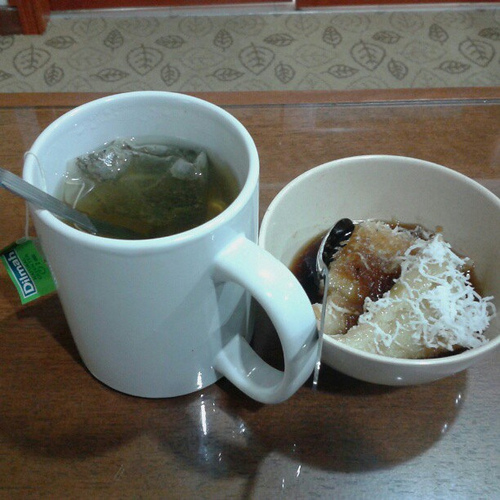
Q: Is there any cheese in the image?
A: Yes, there is cheese.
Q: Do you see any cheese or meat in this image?
A: Yes, there is cheese.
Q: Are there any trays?
A: No, there are no trays.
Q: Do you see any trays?
A: No, there are no trays.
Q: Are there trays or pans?
A: No, there are no trays or pans.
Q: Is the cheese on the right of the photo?
A: Yes, the cheese is on the right of the image.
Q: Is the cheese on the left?
A: No, the cheese is on the right of the image.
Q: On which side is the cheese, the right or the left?
A: The cheese is on the right of the image.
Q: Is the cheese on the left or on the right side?
A: The cheese is on the right of the image.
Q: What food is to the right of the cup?
A: The food is cheese.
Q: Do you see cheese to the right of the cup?
A: Yes, there is cheese to the right of the cup.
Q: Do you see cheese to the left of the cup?
A: No, the cheese is to the right of the cup.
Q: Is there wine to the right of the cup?
A: No, there is cheese to the right of the cup.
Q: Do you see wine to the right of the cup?
A: No, there is cheese to the right of the cup.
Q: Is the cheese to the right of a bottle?
A: No, the cheese is to the right of the cup.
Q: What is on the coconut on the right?
A: The cheese is on the coconut.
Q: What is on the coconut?
A: The cheese is on the coconut.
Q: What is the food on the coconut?
A: The food is cheese.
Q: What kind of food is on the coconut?
A: The food is cheese.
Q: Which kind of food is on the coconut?
A: The food is cheese.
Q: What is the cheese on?
A: The cheese is on the coconut.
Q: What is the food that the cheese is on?
A: The food is a coconut.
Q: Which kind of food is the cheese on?
A: The cheese is on the coconut.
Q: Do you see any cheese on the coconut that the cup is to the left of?
A: Yes, there is cheese on the coconut.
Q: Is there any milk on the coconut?
A: No, there is cheese on the coconut.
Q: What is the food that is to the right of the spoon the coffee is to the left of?
A: The food is cheese.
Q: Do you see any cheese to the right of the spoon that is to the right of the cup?
A: Yes, there is cheese to the right of the spoon.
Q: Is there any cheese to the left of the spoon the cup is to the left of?
A: No, the cheese is to the right of the spoon.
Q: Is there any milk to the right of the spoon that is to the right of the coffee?
A: No, there is cheese to the right of the spoon.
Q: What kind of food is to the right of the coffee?
A: The food is cheese.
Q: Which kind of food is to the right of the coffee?
A: The food is cheese.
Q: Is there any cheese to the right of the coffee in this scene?
A: Yes, there is cheese to the right of the coffee.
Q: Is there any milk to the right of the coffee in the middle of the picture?
A: No, there is cheese to the right of the coffee.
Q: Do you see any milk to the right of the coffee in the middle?
A: No, there is cheese to the right of the coffee.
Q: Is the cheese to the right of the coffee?
A: Yes, the cheese is to the right of the coffee.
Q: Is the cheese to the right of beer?
A: No, the cheese is to the right of the coffee.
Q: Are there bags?
A: Yes, there is a bag.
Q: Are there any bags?
A: Yes, there is a bag.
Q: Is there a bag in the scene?
A: Yes, there is a bag.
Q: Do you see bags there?
A: Yes, there is a bag.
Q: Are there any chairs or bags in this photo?
A: Yes, there is a bag.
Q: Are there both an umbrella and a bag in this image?
A: No, there is a bag but no umbrellas.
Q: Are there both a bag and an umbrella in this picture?
A: No, there is a bag but no umbrellas.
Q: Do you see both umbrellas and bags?
A: No, there is a bag but no umbrellas.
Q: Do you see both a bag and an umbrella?
A: No, there is a bag but no umbrellas.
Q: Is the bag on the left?
A: Yes, the bag is on the left of the image.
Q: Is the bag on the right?
A: No, the bag is on the left of the image.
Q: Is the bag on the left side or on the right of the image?
A: The bag is on the left of the image.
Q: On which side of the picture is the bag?
A: The bag is on the left of the image.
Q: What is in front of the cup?
A: The bag is in front of the cup.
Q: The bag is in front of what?
A: The bag is in front of the cup.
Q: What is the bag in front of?
A: The bag is in front of the cup.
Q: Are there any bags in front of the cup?
A: Yes, there is a bag in front of the cup.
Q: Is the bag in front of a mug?
A: No, the bag is in front of the cup.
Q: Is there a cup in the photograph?
A: Yes, there is a cup.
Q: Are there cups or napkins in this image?
A: Yes, there is a cup.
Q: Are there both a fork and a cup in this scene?
A: No, there is a cup but no forks.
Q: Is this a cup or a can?
A: This is a cup.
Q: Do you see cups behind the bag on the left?
A: Yes, there is a cup behind the bag.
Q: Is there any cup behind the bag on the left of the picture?
A: Yes, there is a cup behind the bag.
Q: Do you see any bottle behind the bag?
A: No, there is a cup behind the bag.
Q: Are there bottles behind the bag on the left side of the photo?
A: No, there is a cup behind the bag.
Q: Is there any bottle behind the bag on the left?
A: No, there is a cup behind the bag.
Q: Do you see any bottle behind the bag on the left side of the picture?
A: No, there is a cup behind the bag.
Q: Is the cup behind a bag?
A: Yes, the cup is behind a bag.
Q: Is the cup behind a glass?
A: No, the cup is behind a bag.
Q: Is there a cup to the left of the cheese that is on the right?
A: Yes, there is a cup to the left of the cheese.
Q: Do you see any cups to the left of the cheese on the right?
A: Yes, there is a cup to the left of the cheese.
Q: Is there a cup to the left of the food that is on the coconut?
A: Yes, there is a cup to the left of the cheese.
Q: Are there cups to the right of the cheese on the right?
A: No, the cup is to the left of the cheese.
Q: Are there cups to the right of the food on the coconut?
A: No, the cup is to the left of the cheese.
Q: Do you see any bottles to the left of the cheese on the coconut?
A: No, there is a cup to the left of the cheese.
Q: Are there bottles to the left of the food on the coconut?
A: No, there is a cup to the left of the cheese.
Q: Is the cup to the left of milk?
A: No, the cup is to the left of the cheese.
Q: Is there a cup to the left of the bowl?
A: Yes, there is a cup to the left of the bowl.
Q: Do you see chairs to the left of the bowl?
A: No, there is a cup to the left of the bowl.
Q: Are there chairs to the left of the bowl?
A: No, there is a cup to the left of the bowl.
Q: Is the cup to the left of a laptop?
A: No, the cup is to the left of the bowl.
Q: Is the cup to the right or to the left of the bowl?
A: The cup is to the left of the bowl.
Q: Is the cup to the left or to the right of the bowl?
A: The cup is to the left of the bowl.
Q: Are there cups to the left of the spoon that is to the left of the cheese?
A: Yes, there is a cup to the left of the spoon.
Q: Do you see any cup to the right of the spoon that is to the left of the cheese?
A: No, the cup is to the left of the spoon.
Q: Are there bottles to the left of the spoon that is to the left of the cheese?
A: No, there is a cup to the left of the spoon.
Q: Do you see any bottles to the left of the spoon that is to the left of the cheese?
A: No, there is a cup to the left of the spoon.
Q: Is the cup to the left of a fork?
A: No, the cup is to the left of the spoon.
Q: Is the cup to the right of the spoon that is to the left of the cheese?
A: No, the cup is to the left of the spoon.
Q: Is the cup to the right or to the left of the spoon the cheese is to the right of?
A: The cup is to the left of the spoon.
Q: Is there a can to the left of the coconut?
A: No, there is a cup to the left of the coconut.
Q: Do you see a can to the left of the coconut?
A: No, there is a cup to the left of the coconut.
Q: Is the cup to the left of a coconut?
A: Yes, the cup is to the left of a coconut.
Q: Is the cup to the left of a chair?
A: No, the cup is to the left of a coconut.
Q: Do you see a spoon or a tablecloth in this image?
A: Yes, there is a spoon.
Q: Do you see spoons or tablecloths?
A: Yes, there is a spoon.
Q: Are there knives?
A: No, there are no knives.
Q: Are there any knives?
A: No, there are no knives.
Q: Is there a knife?
A: No, there are no knives.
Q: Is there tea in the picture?
A: Yes, there is tea.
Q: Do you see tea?
A: Yes, there is tea.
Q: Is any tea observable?
A: Yes, there is tea.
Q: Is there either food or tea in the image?
A: Yes, there is tea.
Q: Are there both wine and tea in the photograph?
A: No, there is tea but no wine.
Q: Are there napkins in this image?
A: No, there are no napkins.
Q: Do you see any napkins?
A: No, there are no napkins.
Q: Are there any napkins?
A: No, there are no napkins.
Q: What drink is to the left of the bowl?
A: The drink is tea.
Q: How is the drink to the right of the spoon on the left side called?
A: The drink is tea.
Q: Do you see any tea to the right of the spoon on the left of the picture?
A: Yes, there is tea to the right of the spoon.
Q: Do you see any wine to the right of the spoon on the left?
A: No, there is tea to the right of the spoon.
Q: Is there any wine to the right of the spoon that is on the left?
A: No, there is tea to the right of the spoon.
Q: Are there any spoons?
A: Yes, there is a spoon.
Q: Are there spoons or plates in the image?
A: Yes, there is a spoon.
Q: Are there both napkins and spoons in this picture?
A: No, there is a spoon but no napkins.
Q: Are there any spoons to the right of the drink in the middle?
A: Yes, there is a spoon to the right of the coffee.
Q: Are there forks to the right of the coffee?
A: No, there is a spoon to the right of the coffee.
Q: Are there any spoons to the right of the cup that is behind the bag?
A: Yes, there is a spoon to the right of the cup.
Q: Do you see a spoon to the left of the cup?
A: No, the spoon is to the right of the cup.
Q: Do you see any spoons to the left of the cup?
A: No, the spoon is to the right of the cup.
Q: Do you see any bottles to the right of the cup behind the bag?
A: No, there is a spoon to the right of the cup.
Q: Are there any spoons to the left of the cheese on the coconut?
A: Yes, there is a spoon to the left of the cheese.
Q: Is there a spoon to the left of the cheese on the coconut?
A: Yes, there is a spoon to the left of the cheese.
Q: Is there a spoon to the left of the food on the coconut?
A: Yes, there is a spoon to the left of the cheese.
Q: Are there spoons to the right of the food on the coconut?
A: No, the spoon is to the left of the cheese.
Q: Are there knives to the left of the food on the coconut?
A: No, there is a spoon to the left of the cheese.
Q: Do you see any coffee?
A: Yes, there is coffee.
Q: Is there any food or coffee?
A: Yes, there is coffee.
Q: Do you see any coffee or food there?
A: Yes, there is coffee.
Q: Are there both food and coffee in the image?
A: Yes, there are both coffee and food.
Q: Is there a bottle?
A: No, there are no bottles.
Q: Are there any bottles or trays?
A: No, there are no bottles or trays.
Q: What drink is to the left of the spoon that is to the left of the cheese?
A: The drink is coffee.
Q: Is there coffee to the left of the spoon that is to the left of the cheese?
A: Yes, there is coffee to the left of the spoon.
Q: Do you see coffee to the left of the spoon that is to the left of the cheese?
A: Yes, there is coffee to the left of the spoon.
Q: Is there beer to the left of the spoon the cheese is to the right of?
A: No, there is coffee to the left of the spoon.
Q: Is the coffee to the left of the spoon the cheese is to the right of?
A: Yes, the coffee is to the left of the spoon.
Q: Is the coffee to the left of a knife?
A: No, the coffee is to the left of the spoon.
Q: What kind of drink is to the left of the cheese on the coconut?
A: The drink is coffee.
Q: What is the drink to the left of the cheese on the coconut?
A: The drink is coffee.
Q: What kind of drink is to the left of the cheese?
A: The drink is coffee.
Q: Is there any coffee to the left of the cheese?
A: Yes, there is coffee to the left of the cheese.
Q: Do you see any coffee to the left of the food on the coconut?
A: Yes, there is coffee to the left of the cheese.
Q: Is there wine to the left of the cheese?
A: No, there is coffee to the left of the cheese.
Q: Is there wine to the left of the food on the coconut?
A: No, there is coffee to the left of the cheese.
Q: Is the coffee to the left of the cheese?
A: Yes, the coffee is to the left of the cheese.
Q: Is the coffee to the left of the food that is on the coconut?
A: Yes, the coffee is to the left of the cheese.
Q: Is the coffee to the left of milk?
A: No, the coffee is to the left of the cheese.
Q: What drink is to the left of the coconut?
A: The drink is coffee.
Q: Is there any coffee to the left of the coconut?
A: Yes, there is coffee to the left of the coconut.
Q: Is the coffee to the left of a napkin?
A: No, the coffee is to the left of the coconut.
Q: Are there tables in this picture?
A: Yes, there is a table.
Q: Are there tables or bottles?
A: Yes, there is a table.